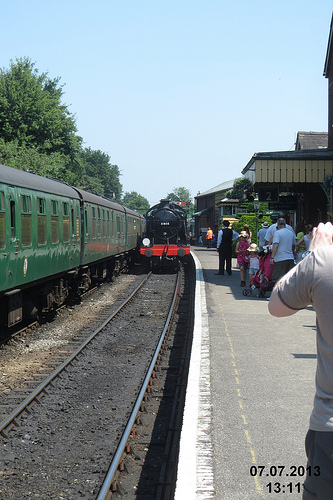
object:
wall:
[194, 190, 233, 244]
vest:
[206, 229, 213, 239]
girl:
[235, 231, 250, 288]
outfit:
[237, 240, 251, 269]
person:
[217, 218, 238, 276]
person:
[257, 220, 269, 254]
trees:
[0, 53, 79, 187]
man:
[266, 218, 297, 302]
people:
[268, 217, 333, 499]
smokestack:
[160, 198, 171, 206]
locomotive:
[141, 190, 191, 274]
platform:
[174, 234, 331, 499]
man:
[206, 225, 213, 248]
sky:
[0, 0, 333, 210]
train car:
[123, 205, 140, 251]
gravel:
[45, 340, 52, 348]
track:
[1, 250, 188, 499]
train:
[139, 198, 192, 257]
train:
[1, 161, 149, 345]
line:
[171, 243, 200, 499]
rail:
[0, 265, 153, 435]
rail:
[96, 262, 180, 499]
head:
[275, 216, 287, 229]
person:
[246, 243, 259, 285]